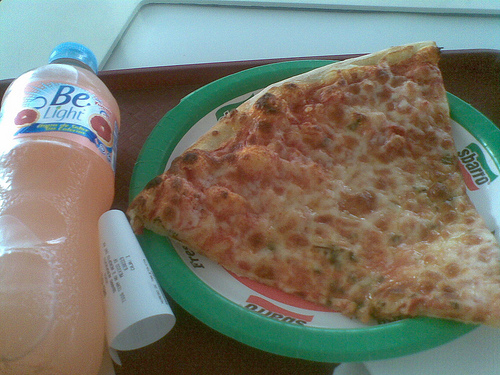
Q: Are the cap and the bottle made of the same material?
A: Yes, both the cap and the bottle are made of plastic.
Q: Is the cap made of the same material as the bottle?
A: Yes, both the cap and the bottle are made of plastic.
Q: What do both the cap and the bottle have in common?
A: The material, both the cap and the bottle are plastic.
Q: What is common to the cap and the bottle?
A: The material, both the cap and the bottle are plastic.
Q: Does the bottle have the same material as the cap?
A: Yes, both the bottle and the cap are made of plastic.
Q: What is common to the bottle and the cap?
A: The material, both the bottle and the cap are plastic.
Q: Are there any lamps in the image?
A: No, there are no lamps.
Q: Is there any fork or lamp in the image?
A: No, there are no lamps or forks.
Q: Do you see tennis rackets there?
A: No, there are no tennis rackets.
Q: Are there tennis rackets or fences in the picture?
A: No, there are no tennis rackets or fences.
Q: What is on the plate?
A: The logo is on the plate.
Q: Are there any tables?
A: Yes, there is a table.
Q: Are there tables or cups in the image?
A: Yes, there is a table.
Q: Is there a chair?
A: No, there are no chairs.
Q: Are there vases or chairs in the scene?
A: No, there are no chairs or vases.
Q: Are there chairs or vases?
A: No, there are no chairs or vases.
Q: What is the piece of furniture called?
A: The piece of furniture is a table.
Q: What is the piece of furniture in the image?
A: The piece of furniture is a table.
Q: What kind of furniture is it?
A: The piece of furniture is a table.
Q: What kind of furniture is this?
A: This is a table.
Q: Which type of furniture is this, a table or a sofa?
A: This is a table.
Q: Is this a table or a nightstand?
A: This is a table.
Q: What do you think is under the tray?
A: The table is under the tray.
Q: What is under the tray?
A: The table is under the tray.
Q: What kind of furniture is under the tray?
A: The piece of furniture is a table.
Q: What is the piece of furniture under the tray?
A: The piece of furniture is a table.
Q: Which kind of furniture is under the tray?
A: The piece of furniture is a table.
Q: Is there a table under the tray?
A: Yes, there is a table under the tray.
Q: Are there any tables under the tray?
A: Yes, there is a table under the tray.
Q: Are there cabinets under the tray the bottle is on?
A: No, there is a table under the tray.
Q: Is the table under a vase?
A: No, the table is under the tray.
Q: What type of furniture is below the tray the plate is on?
A: The piece of furniture is a table.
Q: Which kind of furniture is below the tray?
A: The piece of furniture is a table.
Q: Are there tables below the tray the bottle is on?
A: Yes, there is a table below the tray.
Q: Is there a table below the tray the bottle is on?
A: Yes, there is a table below the tray.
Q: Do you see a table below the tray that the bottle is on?
A: Yes, there is a table below the tray.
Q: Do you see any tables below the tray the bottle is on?
A: Yes, there is a table below the tray.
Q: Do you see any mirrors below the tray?
A: No, there is a table below the tray.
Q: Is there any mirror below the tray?
A: No, there is a table below the tray.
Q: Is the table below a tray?
A: Yes, the table is below a tray.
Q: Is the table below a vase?
A: No, the table is below a tray.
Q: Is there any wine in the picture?
A: No, there is no wine.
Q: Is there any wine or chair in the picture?
A: No, there are no wine or chairs.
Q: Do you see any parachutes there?
A: No, there are no parachutes.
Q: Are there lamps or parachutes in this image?
A: No, there are no parachutes or lamps.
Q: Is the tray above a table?
A: Yes, the tray is above a table.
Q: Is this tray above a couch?
A: No, the tray is above a table.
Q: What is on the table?
A: The tray is on the table.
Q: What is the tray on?
A: The tray is on the table.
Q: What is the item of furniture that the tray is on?
A: The piece of furniture is a table.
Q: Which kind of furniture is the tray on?
A: The tray is on the table.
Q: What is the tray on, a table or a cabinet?
A: The tray is on a table.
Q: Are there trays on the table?
A: Yes, there is a tray on the table.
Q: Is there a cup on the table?
A: No, there is a tray on the table.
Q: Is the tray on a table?
A: Yes, the tray is on a table.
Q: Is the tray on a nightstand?
A: No, the tray is on a table.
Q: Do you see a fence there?
A: No, there are no fences.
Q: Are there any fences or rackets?
A: No, there are no fences or rackets.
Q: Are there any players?
A: No, there are no players.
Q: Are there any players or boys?
A: No, there are no players or boys.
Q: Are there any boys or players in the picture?
A: No, there are no players or boys.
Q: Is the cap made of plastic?
A: Yes, the cap is made of plastic.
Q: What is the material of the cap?
A: The cap is made of plastic.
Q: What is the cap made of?
A: The cap is made of plastic.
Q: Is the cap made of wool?
A: No, the cap is made of plastic.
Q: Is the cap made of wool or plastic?
A: The cap is made of plastic.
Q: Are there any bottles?
A: Yes, there is a bottle.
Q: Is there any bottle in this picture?
A: Yes, there is a bottle.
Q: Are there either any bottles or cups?
A: Yes, there is a bottle.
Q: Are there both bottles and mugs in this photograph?
A: No, there is a bottle but no mugs.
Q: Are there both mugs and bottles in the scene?
A: No, there is a bottle but no mugs.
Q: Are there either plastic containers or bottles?
A: Yes, there is a plastic bottle.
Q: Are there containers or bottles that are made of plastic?
A: Yes, the bottle is made of plastic.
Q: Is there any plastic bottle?
A: Yes, there is a bottle that is made of plastic.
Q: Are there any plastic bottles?
A: Yes, there is a bottle that is made of plastic.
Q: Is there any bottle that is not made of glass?
A: Yes, there is a bottle that is made of plastic.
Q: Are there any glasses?
A: No, there are no glasses.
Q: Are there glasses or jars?
A: No, there are no glasses or jars.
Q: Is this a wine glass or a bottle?
A: This is a bottle.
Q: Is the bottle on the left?
A: Yes, the bottle is on the left of the image.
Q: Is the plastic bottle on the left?
A: Yes, the bottle is on the left of the image.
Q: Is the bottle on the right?
A: No, the bottle is on the left of the image.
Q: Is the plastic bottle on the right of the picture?
A: No, the bottle is on the left of the image.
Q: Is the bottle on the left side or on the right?
A: The bottle is on the left of the image.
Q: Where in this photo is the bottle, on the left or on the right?
A: The bottle is on the left of the image.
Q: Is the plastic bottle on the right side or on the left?
A: The bottle is on the left of the image.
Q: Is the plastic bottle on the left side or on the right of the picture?
A: The bottle is on the left of the image.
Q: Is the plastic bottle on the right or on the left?
A: The bottle is on the left of the image.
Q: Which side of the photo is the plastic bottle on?
A: The bottle is on the left of the image.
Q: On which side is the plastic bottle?
A: The bottle is on the left of the image.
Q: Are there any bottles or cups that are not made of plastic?
A: No, there is a bottle but it is made of plastic.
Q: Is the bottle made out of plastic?
A: Yes, the bottle is made of plastic.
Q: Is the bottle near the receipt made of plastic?
A: Yes, the bottle is made of plastic.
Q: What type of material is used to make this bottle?
A: The bottle is made of plastic.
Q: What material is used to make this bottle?
A: The bottle is made of plastic.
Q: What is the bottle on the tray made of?
A: The bottle is made of plastic.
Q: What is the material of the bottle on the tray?
A: The bottle is made of plastic.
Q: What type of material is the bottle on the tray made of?
A: The bottle is made of plastic.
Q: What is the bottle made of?
A: The bottle is made of plastic.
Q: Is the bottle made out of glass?
A: No, the bottle is made of plastic.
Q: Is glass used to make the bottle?
A: No, the bottle is made of plastic.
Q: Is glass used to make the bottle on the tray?
A: No, the bottle is made of plastic.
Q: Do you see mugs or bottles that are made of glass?
A: No, there is a bottle but it is made of plastic.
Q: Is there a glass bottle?
A: No, there is a bottle but it is made of plastic.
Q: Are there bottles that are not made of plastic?
A: No, there is a bottle but it is made of plastic.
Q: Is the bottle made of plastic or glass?
A: The bottle is made of plastic.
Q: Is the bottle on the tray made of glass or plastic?
A: The bottle is made of plastic.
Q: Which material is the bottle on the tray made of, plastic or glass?
A: The bottle is made of plastic.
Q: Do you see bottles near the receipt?
A: Yes, there is a bottle near the receipt.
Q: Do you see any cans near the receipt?
A: No, there is a bottle near the receipt.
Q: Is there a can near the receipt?
A: No, there is a bottle near the receipt.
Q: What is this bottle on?
A: The bottle is on the tray.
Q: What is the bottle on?
A: The bottle is on the tray.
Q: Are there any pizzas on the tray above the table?
A: No, there is a bottle on the tray.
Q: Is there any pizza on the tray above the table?
A: No, there is a bottle on the tray.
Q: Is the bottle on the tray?
A: Yes, the bottle is on the tray.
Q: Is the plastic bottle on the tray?
A: Yes, the bottle is on the tray.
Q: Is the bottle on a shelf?
A: No, the bottle is on the tray.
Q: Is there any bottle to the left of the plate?
A: Yes, there is a bottle to the left of the plate.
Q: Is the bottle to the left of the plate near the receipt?
A: Yes, the bottle is to the left of the plate.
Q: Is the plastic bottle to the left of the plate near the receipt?
A: Yes, the bottle is to the left of the plate.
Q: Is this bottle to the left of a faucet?
A: No, the bottle is to the left of the plate.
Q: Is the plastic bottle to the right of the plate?
A: No, the bottle is to the left of the plate.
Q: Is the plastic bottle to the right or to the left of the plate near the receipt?
A: The bottle is to the left of the plate.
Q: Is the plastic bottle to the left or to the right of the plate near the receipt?
A: The bottle is to the left of the plate.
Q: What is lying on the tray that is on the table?
A: The bottle is lying on the tray.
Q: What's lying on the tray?
A: The bottle is lying on the tray.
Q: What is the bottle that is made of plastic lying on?
A: The bottle is lying on the tray.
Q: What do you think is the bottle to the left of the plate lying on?
A: The bottle is lying on the tray.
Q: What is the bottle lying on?
A: The bottle is lying on the tray.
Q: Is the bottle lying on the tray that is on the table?
A: Yes, the bottle is lying on the tray.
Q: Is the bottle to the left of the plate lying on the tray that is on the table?
A: Yes, the bottle is lying on the tray.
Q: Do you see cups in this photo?
A: No, there are no cups.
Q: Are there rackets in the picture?
A: No, there are no rackets.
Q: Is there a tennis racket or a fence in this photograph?
A: No, there are no rackets or fences.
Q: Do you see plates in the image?
A: Yes, there is a plate.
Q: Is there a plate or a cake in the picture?
A: Yes, there is a plate.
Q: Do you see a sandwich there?
A: No, there are no sandwiches.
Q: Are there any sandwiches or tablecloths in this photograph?
A: No, there are no sandwiches or tablecloths.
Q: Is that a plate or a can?
A: That is a plate.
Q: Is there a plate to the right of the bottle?
A: Yes, there is a plate to the right of the bottle.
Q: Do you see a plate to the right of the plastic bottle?
A: Yes, there is a plate to the right of the bottle.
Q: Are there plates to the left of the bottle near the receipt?
A: No, the plate is to the right of the bottle.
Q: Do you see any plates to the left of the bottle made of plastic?
A: No, the plate is to the right of the bottle.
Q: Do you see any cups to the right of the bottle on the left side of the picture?
A: No, there is a plate to the right of the bottle.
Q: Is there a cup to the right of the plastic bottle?
A: No, there is a plate to the right of the bottle.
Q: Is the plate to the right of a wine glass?
A: No, the plate is to the right of the bottle.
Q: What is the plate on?
A: The plate is on the tray.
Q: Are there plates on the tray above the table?
A: Yes, there is a plate on the tray.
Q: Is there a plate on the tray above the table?
A: Yes, there is a plate on the tray.